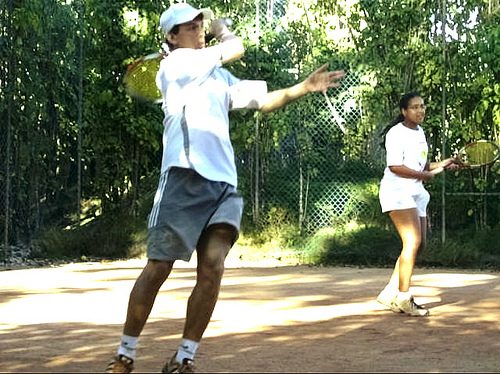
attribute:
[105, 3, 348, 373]
person — playing, exercising, enjoying, white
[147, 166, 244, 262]
pants — short, grey, white, gray, lifted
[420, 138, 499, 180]
racket — neon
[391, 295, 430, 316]
sneaker — white, brown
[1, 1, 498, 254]
fence — dirty, tall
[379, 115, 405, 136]
braid — black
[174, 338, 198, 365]
socks — white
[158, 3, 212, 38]
cap — white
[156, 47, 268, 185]
shirt — white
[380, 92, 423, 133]
hair — black